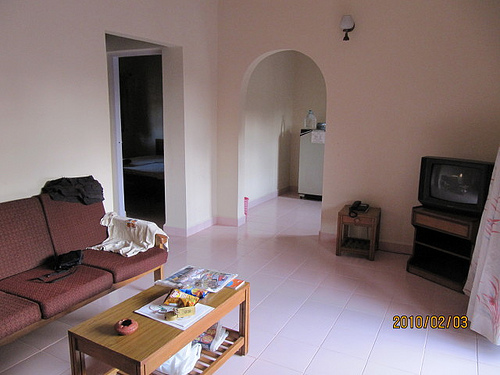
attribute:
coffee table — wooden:
[64, 324, 167, 370]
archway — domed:
[234, 48, 340, 104]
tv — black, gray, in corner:
[422, 157, 498, 215]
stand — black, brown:
[408, 206, 471, 295]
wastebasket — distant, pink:
[237, 193, 262, 225]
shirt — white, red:
[95, 209, 169, 269]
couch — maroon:
[10, 202, 102, 239]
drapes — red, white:
[476, 233, 499, 320]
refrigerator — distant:
[299, 132, 336, 200]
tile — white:
[306, 288, 353, 326]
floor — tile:
[237, 241, 303, 261]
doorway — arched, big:
[232, 46, 330, 247]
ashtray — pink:
[106, 320, 148, 333]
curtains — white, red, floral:
[479, 244, 496, 313]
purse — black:
[26, 259, 98, 294]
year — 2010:
[394, 315, 424, 338]